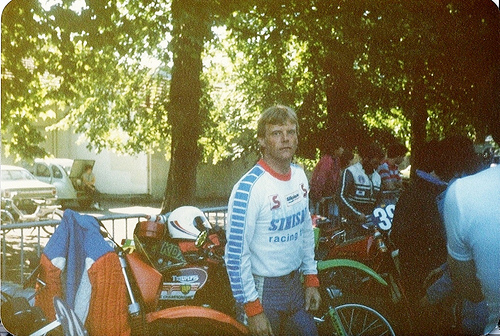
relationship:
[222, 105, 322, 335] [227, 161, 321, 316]
man wears shirt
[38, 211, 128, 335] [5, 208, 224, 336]
jacket on motorcycle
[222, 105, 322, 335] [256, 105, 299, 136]
man has hair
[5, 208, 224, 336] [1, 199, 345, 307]
motorcycle along barrier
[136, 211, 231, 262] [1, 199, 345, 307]
motorcycle along barrier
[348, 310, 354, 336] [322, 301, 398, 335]
spoke on tire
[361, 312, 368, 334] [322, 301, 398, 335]
spoke on tire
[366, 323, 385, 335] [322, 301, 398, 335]
spoke on tire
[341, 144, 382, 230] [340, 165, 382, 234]
man wears jacket